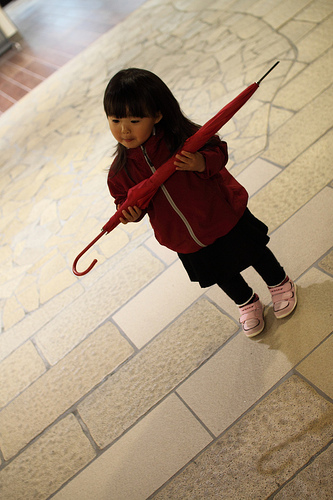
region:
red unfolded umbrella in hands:
[91, 72, 246, 223]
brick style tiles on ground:
[30, 299, 277, 498]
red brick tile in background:
[0, 2, 86, 90]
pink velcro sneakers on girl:
[236, 278, 297, 329]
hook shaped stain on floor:
[240, 394, 329, 485]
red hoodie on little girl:
[101, 147, 269, 241]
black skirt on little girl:
[173, 222, 262, 288]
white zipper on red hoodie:
[136, 139, 205, 254]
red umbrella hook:
[65, 241, 99, 285]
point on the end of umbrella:
[244, 37, 286, 96]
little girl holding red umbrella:
[106, 63, 288, 334]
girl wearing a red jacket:
[99, 67, 251, 265]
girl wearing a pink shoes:
[112, 78, 324, 328]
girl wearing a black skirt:
[112, 73, 312, 329]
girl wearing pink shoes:
[129, 53, 301, 323]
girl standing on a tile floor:
[75, 78, 307, 351]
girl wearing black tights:
[105, 76, 308, 343]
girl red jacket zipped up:
[106, 56, 246, 271]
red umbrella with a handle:
[76, 117, 257, 261]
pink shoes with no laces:
[221, 256, 312, 342]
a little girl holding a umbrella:
[93, 55, 287, 292]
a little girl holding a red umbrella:
[71, 43, 276, 267]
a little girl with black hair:
[85, 49, 216, 180]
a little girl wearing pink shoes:
[142, 87, 295, 415]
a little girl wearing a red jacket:
[98, 77, 202, 247]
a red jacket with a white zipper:
[132, 127, 201, 251]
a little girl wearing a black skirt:
[149, 89, 307, 296]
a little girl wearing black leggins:
[179, 82, 298, 324]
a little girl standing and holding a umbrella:
[105, 37, 253, 485]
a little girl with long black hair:
[96, 58, 193, 177]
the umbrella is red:
[64, 82, 229, 265]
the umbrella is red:
[90, 29, 285, 299]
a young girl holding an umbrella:
[42, 50, 304, 382]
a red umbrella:
[72, 61, 282, 278]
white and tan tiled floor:
[0, 0, 332, 494]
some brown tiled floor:
[6, 0, 106, 104]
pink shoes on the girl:
[226, 275, 299, 353]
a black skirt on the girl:
[178, 212, 263, 283]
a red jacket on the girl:
[102, 128, 258, 242]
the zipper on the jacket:
[136, 147, 205, 245]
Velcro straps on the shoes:
[233, 283, 294, 330]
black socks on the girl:
[216, 250, 288, 309]